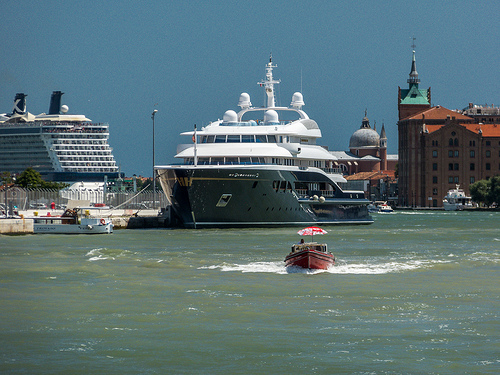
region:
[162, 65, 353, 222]
cruise ship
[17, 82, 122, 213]
cruise ship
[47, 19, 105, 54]
white clouds in blue sky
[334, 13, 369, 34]
white clouds in blue sky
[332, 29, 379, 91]
white clouds in blue sky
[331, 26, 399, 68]
white clouds in blue sky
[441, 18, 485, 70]
white clouds in blue sky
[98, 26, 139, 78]
white clouds in blue sky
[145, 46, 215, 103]
white clouds in blue sky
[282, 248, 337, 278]
Red speed boat on the water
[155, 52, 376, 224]
A private yacht is docked here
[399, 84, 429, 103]
Copper tinned roof top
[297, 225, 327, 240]
Red and white sun umbrella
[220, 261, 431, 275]
The wake of a boat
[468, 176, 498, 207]
A green leaf covered tree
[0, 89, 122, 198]
A cruise ship with many levels of windows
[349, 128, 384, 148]
A gray domed roof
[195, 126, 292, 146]
Bridge of the ship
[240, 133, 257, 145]
A rectangular single pane window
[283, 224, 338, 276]
a boat on the water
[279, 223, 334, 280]
a orange boat on the water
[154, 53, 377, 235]
a gray and white boat on the water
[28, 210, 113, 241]
a white boat on the water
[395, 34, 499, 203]
a red brick building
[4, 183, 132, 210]
a chain link fence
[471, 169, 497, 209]
green trees by the water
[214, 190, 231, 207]
a symbol on the boat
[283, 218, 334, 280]
a red umbrella on a boat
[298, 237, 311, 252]
a person on a boat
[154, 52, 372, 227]
a large ship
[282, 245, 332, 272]
a red boat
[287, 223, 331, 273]
an umbrella on a red boat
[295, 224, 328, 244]
an umbrella on a boat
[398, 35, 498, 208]
a large brick building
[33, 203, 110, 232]
a white boat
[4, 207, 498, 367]
a body of water with many boats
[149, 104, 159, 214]
a light pole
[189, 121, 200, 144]
a flag on the ship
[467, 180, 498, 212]
trees next to the water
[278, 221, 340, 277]
Small boat headed toward the camera.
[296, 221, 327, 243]
A red and white umbrella on top of boat.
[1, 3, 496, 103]
A clear blue cloudless sky.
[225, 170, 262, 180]
Writing on the side of a ship.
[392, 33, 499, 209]
Large brown building along the shore.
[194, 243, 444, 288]
Wake in the water left by boat moving through the water.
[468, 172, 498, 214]
A large bushy green tree.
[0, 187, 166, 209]
Metal fence along the shoreline.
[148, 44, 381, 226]
A large ship docked along the shore.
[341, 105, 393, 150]
A dome on top of building.